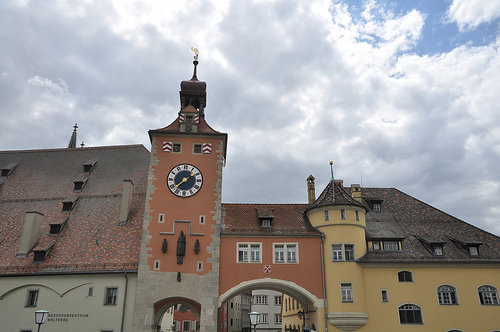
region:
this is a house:
[7, 145, 499, 329]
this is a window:
[236, 237, 263, 262]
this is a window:
[268, 242, 303, 265]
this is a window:
[328, 241, 357, 262]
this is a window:
[339, 277, 360, 305]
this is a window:
[396, 302, 424, 328]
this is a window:
[432, 274, 461, 307]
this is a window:
[478, 280, 498, 312]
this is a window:
[338, 280, 354, 300]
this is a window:
[104, 284, 121, 305]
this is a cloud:
[266, 67, 340, 137]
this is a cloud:
[366, 76, 415, 156]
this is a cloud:
[253, 55, 323, 126]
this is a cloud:
[449, 56, 493, 113]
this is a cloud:
[31, 67, 90, 117]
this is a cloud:
[254, 109, 311, 175]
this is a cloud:
[100, 32, 150, 87]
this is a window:
[275, 240, 301, 260]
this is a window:
[398, 267, 416, 287]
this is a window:
[431, 284, 459, 308]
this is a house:
[0, 141, 497, 330]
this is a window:
[394, 297, 428, 327]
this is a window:
[438, 274, 461, 311]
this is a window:
[469, 271, 499, 303]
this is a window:
[231, 239, 277, 269]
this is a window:
[261, 225, 302, 272]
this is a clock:
[168, 163, 203, 199]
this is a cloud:
[239, 121, 301, 178]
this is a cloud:
[358, 74, 431, 158]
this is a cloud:
[198, 34, 269, 87]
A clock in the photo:
[169, 159, 207, 200]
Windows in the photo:
[433, 282, 498, 307]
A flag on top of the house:
[187, 41, 208, 83]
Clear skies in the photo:
[427, 20, 448, 50]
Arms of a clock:
[169, 169, 199, 187]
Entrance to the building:
[250, 294, 299, 331]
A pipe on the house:
[312, 262, 341, 304]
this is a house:
[6, 144, 449, 328]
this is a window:
[232, 239, 269, 261]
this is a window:
[478, 282, 497, 304]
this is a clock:
[163, 162, 204, 201]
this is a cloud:
[281, 64, 366, 139]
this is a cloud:
[366, 71, 445, 152]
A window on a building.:
[338, 282, 353, 301]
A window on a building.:
[398, 300, 425, 320]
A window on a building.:
[433, 280, 461, 303]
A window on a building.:
[475, 280, 492, 299]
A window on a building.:
[396, 266, 420, 280]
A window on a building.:
[382, 283, 390, 303]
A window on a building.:
[268, 241, 298, 263]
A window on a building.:
[230, 241, 264, 267]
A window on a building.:
[382, 240, 400, 250]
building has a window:
[239, 240, 247, 261]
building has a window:
[249, 241, 259, 260]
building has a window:
[274, 241, 284, 262]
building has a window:
[284, 245, 296, 260]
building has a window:
[335, 242, 343, 259]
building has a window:
[342, 286, 352, 301]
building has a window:
[436, 283, 456, 303]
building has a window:
[479, 284, 497, 305]